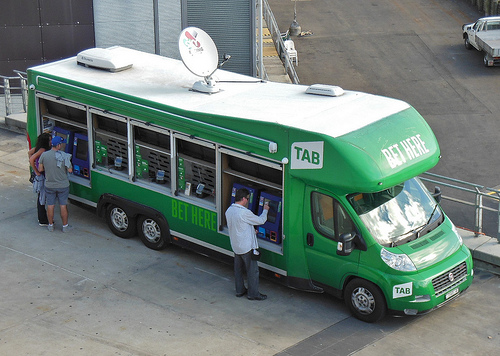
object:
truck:
[25, 45, 473, 324]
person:
[225, 187, 271, 301]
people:
[28, 132, 73, 233]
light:
[380, 247, 418, 271]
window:
[312, 191, 364, 248]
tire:
[343, 278, 387, 323]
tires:
[106, 203, 169, 249]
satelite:
[179, 26, 232, 94]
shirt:
[225, 203, 268, 255]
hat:
[50, 136, 67, 146]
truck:
[462, 16, 500, 67]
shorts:
[45, 184, 70, 205]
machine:
[71, 132, 91, 180]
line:
[271, 319, 403, 354]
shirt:
[33, 174, 48, 206]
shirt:
[38, 150, 73, 188]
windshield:
[348, 176, 443, 247]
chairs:
[282, 40, 298, 67]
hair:
[37, 132, 53, 148]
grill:
[432, 260, 468, 298]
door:
[301, 184, 364, 300]